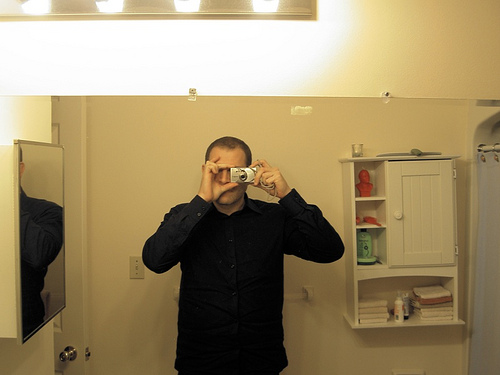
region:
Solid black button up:
[127, 189, 342, 373]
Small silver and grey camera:
[223, 165, 258, 184]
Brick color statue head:
[354, 169, 382, 198]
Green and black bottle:
[351, 228, 376, 263]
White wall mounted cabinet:
[335, 140, 461, 330]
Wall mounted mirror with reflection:
[10, 141, 65, 346]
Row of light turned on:
[7, 0, 322, 24]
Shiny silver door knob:
[59, 345, 76, 361]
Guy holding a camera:
[139, 135, 347, 372]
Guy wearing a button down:
[141, 138, 346, 373]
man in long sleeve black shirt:
[133, 112, 353, 359]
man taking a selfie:
[111, 130, 391, 292]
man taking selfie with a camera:
[124, 125, 396, 340]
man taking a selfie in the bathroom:
[107, 113, 434, 306]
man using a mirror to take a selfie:
[129, 110, 382, 350]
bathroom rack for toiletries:
[328, 118, 496, 374]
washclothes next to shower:
[341, 123, 498, 347]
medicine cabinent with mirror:
[7, 134, 114, 358]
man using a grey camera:
[169, 123, 319, 265]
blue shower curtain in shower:
[434, 104, 499, 374]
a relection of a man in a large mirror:
[115, 120, 377, 372]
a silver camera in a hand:
[213, 162, 264, 189]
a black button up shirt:
[136, 185, 343, 373]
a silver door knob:
[48, 341, 92, 371]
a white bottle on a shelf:
[394, 290, 405, 325]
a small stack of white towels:
[351, 288, 391, 338]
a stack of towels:
[407, 280, 463, 325]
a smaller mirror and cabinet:
[1, 123, 94, 357]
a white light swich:
[119, 242, 154, 287]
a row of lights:
[0, 0, 325, 53]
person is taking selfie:
[137, 138, 346, 373]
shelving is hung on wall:
[339, 141, 464, 337]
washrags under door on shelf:
[356, 282, 454, 325]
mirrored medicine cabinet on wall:
[1, 136, 67, 348]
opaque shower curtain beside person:
[463, 138, 499, 373]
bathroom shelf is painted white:
[336, 148, 466, 330]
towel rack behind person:
[176, 280, 316, 312]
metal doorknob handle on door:
[59, 343, 91, 365]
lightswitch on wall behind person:
[128, 255, 146, 281]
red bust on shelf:
[353, 166, 375, 200]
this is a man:
[153, 126, 313, 372]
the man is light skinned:
[206, 170, 229, 196]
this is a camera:
[226, 165, 258, 180]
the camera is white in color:
[233, 167, 253, 174]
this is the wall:
[99, 128, 179, 186]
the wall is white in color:
[94, 118, 159, 158]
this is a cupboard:
[359, 152, 464, 327]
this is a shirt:
[225, 218, 274, 322]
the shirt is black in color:
[213, 232, 259, 293]